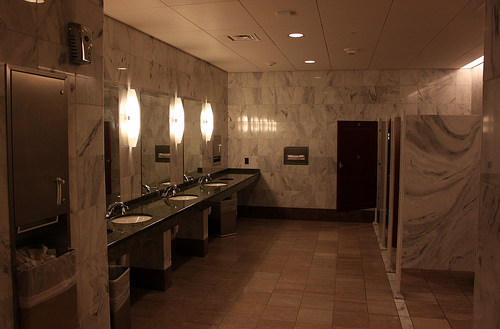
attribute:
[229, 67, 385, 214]
wall — marble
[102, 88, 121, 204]
mirror — vanity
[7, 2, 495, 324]
bathroom — white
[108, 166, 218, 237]
basins — three, wash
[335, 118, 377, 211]
door — closed, black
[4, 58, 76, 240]
towel dispenser — metal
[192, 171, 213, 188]
faucet — silver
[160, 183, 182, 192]
faucet — silver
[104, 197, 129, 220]
faucet — silver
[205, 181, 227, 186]
sink — white, porcelain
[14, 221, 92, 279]
bag — transparent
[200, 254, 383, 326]
tiles — brown, clear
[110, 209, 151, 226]
wash basin — one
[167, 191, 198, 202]
wash basin — one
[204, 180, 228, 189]
wash basin — one